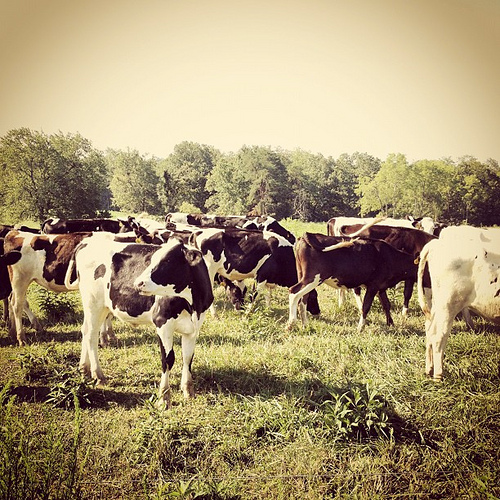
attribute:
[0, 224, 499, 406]
cows — grazing, facing, black, white, standing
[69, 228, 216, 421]
cow — facing, walking, skinny, standing, large, white, black, looking, grazing, brown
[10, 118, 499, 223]
trees — line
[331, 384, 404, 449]
weeds — growing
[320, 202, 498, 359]
group — large